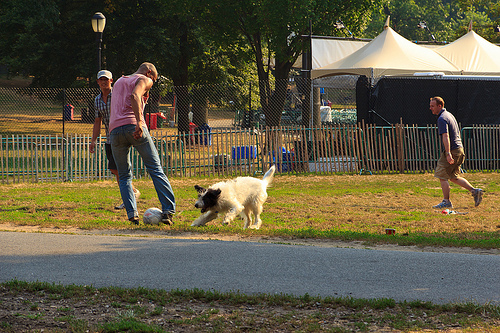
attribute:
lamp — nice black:
[92, 10, 106, 72]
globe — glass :
[93, 17, 105, 31]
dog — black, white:
[182, 159, 313, 239]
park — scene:
[0, 2, 499, 331]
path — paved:
[6, 227, 496, 310]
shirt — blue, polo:
[434, 115, 473, 147]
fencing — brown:
[4, 120, 499, 182]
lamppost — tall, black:
[89, 9, 106, 73]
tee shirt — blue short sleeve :
[436, 112, 461, 148]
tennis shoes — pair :
[428, 186, 483, 212]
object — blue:
[264, 143, 291, 170]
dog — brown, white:
[185, 166, 275, 233]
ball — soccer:
[128, 195, 173, 238]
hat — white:
[98, 67, 113, 79]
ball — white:
[135, 202, 172, 227]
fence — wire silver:
[0, 120, 495, 175]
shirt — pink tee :
[106, 69, 152, 123]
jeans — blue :
[103, 123, 181, 214]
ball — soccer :
[141, 200, 165, 227]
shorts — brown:
[424, 145, 471, 177]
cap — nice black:
[94, 63, 112, 78]